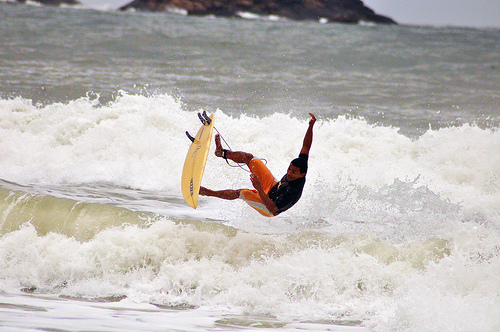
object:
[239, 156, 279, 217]
orange shorts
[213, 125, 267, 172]
rope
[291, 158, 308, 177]
hair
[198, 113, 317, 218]
guy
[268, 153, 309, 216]
black shirt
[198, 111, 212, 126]
fin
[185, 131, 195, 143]
fin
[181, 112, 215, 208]
board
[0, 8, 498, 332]
ocean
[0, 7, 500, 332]
water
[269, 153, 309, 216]
shirt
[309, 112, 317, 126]
hand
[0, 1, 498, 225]
air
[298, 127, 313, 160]
arm